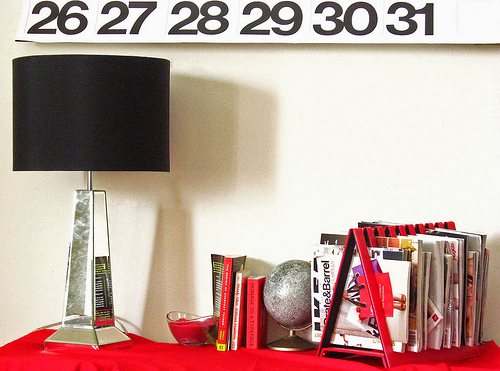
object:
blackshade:
[11, 55, 170, 172]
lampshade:
[11, 54, 170, 172]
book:
[245, 275, 268, 350]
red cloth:
[5, 325, 495, 367]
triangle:
[316, 228, 395, 368]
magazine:
[358, 222, 467, 347]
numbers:
[240, 1, 433, 35]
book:
[319, 233, 423, 353]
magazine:
[479, 247, 489, 344]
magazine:
[443, 254, 454, 349]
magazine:
[310, 220, 489, 353]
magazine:
[444, 239, 452, 350]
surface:
[29, 337, 212, 364]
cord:
[34, 316, 126, 334]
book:
[229, 270, 249, 351]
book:
[210, 254, 245, 352]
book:
[90, 256, 115, 329]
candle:
[166, 311, 218, 347]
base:
[42, 189, 131, 355]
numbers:
[26, 0, 433, 35]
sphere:
[263, 259, 311, 326]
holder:
[266, 321, 313, 352]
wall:
[0, 0, 500, 349]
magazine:
[466, 251, 478, 347]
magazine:
[454, 240, 463, 348]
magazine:
[427, 296, 443, 335]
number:
[312, 1, 377, 34]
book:
[310, 243, 411, 354]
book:
[424, 242, 444, 350]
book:
[319, 255, 411, 344]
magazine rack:
[316, 221, 481, 368]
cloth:
[0, 328, 500, 371]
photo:
[0, 0, 500, 371]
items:
[0, 44, 500, 371]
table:
[0, 328, 500, 371]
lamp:
[11, 54, 169, 354]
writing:
[321, 261, 331, 326]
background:
[0, 0, 500, 46]